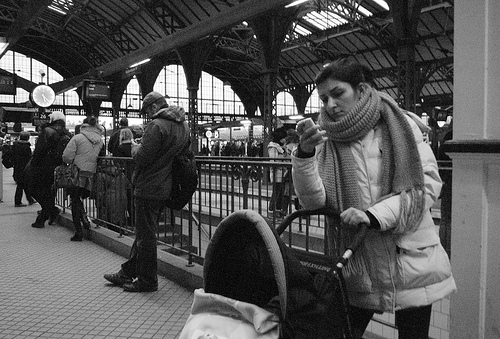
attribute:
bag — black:
[167, 152, 197, 215]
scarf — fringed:
[302, 90, 462, 227]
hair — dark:
[313, 53, 395, 100]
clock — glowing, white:
[31, 82, 66, 116]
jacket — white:
[313, 145, 457, 306]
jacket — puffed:
[291, 115, 430, 209]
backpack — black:
[170, 143, 202, 218]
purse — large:
[49, 158, 74, 188]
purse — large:
[49, 157, 78, 182]